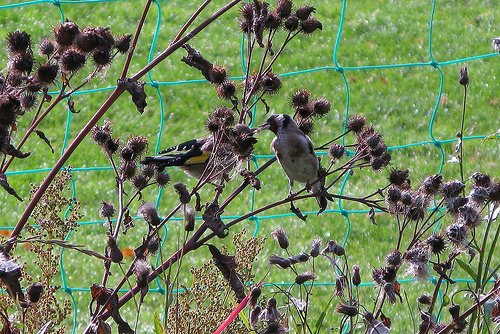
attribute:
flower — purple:
[77, 31, 101, 53]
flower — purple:
[291, 90, 364, 138]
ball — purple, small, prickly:
[268, 227, 292, 249]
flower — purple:
[87, 119, 114, 144]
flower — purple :
[388, 167, 410, 184]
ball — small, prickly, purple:
[93, 46, 119, 70]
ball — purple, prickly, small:
[472, 169, 491, 188]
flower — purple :
[64, 46, 85, 73]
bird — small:
[250, 99, 347, 222]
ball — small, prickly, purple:
[334, 108, 385, 142]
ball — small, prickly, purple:
[28, 279, 47, 300]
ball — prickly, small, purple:
[373, 257, 400, 287]